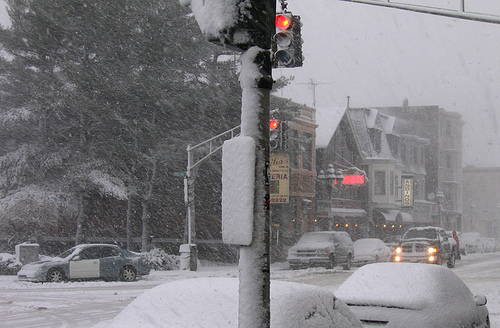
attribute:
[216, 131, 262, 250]
sign — covered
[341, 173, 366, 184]
sign — red, lit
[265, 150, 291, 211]
sign — white , red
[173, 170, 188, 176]
road sign — green, white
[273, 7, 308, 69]
traffic light — red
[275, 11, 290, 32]
light — red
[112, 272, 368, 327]
car — parked, covered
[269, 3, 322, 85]
stoplight — red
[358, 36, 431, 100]
sky — blue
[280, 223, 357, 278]
suv — parked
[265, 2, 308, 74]
traffic signal — lit up , red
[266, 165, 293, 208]
sign — white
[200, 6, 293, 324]
pole — metal, covered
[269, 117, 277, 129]
light — red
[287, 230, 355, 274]
suv — parked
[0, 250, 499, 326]
road — snowy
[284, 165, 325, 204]
wall — brown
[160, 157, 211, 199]
street sign — green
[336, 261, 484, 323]
car — parked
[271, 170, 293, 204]
lettering — black